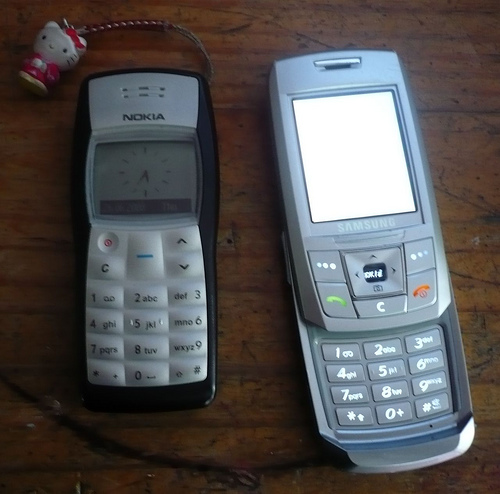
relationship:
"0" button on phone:
[124, 362, 164, 384] [70, 66, 220, 413]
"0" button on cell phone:
[375, 406, 413, 422] [255, 41, 482, 478]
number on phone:
[166, 282, 204, 304] [66, 50, 227, 398]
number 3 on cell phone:
[403, 328, 446, 358] [268, 48, 476, 476]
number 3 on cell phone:
[413, 337, 423, 349] [255, 41, 482, 478]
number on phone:
[194, 290, 201, 300] [70, 60, 219, 410]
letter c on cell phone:
[352, 291, 410, 319] [268, 48, 476, 476]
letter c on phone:
[101, 264, 110, 273] [70, 60, 219, 410]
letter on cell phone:
[370, 294, 395, 313] [255, 41, 482, 478]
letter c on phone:
[85, 253, 131, 283] [70, 60, 219, 410]